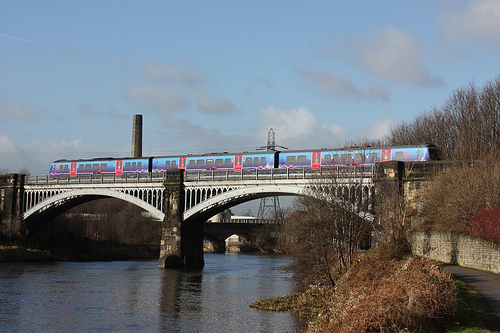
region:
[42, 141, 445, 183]
red and blue train with red doors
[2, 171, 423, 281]
grey metal and stone train bridge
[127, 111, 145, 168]
tall smoke stack in the distance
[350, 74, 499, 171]
leafless barren trees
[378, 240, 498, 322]
asphalt paved walk way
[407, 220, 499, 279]
grey stone wall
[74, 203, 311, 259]
bridge in the distance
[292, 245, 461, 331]
orange coloured dead grass and bushes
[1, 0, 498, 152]
partly cloudy blue sky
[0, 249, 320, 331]
reflective flowing river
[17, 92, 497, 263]
a train on a bridge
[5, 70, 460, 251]
a passenger train on a bridge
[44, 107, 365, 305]
a train above the water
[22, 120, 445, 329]
a bridge above the water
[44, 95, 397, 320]
a train on a bridge above the water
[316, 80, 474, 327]
area full of trees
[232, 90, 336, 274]
a tall power pole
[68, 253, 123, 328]
a body of water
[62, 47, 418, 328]
a train in the day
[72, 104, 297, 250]
a train during the day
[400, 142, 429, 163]
this is a train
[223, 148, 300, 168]
the train is long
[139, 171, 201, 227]
this is a bridge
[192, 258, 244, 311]
water is under the bridge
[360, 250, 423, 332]
the grass is dry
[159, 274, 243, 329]
the water is calm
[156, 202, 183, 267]
the pillar is stone like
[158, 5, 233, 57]
the sky is blue in color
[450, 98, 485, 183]
the branches are dry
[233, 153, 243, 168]
the door is closed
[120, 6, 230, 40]
this is the sky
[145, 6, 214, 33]
the sky is blue in color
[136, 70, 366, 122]
the sky has some clouds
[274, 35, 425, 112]
the clouds are white in color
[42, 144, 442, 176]
this is a train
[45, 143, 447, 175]
the train is long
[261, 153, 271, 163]
the train is blue in color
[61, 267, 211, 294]
this is the water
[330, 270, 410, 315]
this is a hedge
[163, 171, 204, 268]
stone grey bridge support column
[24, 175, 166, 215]
metal and stone train bridge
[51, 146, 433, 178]
red and blue train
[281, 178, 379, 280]
tree with no leaves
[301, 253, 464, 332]
hill with dried grass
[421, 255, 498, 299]
asphalt walking trail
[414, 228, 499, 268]
grey stone barrier wall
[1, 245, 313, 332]
river under bridge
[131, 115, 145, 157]
grey metal smoke stack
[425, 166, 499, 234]
bushes with no leaves